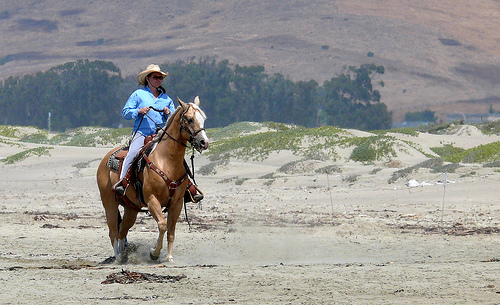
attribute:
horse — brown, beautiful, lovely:
[97, 96, 209, 263]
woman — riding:
[115, 63, 204, 201]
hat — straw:
[139, 64, 169, 85]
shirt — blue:
[122, 85, 176, 136]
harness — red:
[117, 147, 188, 212]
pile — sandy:
[217, 158, 362, 188]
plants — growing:
[1, 121, 499, 168]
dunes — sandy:
[0, 121, 499, 194]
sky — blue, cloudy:
[2, 1, 500, 130]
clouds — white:
[2, 1, 499, 131]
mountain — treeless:
[0, 0, 499, 122]